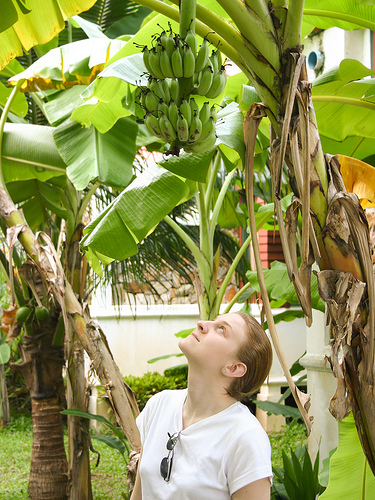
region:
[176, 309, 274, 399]
Head of a person who is looking up.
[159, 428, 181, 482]
Dark sunglasses hanging off a persons shirt.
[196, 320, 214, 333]
Nose of a person looking up.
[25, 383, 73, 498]
Brown base of a banana tree.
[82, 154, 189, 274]
Large leaf of a banana tree.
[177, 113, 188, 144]
Unripened banana on a tree.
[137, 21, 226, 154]
Bunch of unripe green bananas.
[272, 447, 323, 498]
Tall thin green leaves.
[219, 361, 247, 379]
Left ear of a person looking up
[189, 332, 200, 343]
Mouth of a person looking up.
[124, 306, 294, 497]
woman looking up at fruit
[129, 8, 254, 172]
bananas hanging from tree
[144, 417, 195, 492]
black sunglasses hung in woman's shirt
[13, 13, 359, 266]
green and brown banana tree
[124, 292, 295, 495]
woman with blonde hair in white t-shirt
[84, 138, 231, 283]
large green leaves of banana tree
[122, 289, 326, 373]
tall white fence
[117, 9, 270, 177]
bunch of bananas not ripe yet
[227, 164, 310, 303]
red building behind trees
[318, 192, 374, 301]
brown dead leaves of banana tree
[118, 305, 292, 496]
a person looking up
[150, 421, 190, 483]
folded sunglasses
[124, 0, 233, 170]
a banana cluster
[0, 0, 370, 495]
multiple banana trees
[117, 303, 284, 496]
a person wearing a white t-shirt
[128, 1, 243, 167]
the bananas are green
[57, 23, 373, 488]
a white structure behind person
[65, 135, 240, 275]
a large green leaf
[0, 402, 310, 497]
a grassy area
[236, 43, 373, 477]
many dried leaves and one yellow leaf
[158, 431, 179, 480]
Sunglasses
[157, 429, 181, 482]
Black pair of sunglasses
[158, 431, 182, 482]
Sunglasses hanging from t-shirt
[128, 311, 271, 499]
Girl looking up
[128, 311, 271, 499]
Girl wearing a white t-shirt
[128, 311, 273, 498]
Girl looking up with sunglasses hanging from her shirt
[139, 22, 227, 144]
Bunch of Banana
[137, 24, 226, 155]
Bunch of banana hanging from the tree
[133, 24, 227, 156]
Bunch of green banana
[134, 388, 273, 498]
White t-shirt with sunglasses on it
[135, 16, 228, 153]
Large bunch of unripe bananas.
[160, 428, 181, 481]
Sunglasses on the front of a persons shirt.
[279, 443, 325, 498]
Long leaves growing.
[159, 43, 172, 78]
Green unripe banana.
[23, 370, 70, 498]
Brown tree trunk.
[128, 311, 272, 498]
Person looking up.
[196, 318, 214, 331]
Nose of a person looking up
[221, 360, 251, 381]
Left ear of a person.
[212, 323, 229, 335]
Left eye of a person looking up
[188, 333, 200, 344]
Mouth of a person looking up